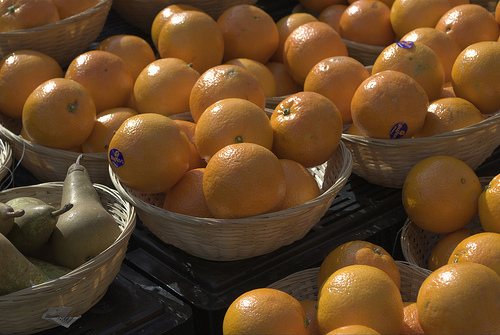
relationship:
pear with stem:
[46, 159, 128, 273] [73, 149, 89, 162]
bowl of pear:
[0, 177, 138, 333] [47, 149, 127, 268]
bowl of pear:
[0, 177, 138, 333] [0, 188, 74, 252]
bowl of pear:
[0, 177, 138, 333] [0, 224, 60, 295]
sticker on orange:
[382, 118, 410, 142] [347, 68, 430, 141]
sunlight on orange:
[144, 63, 165, 78] [128, 56, 206, 117]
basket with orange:
[103, 109, 360, 266] [196, 136, 287, 221]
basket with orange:
[103, 109, 360, 266] [108, 110, 195, 200]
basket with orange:
[103, 109, 360, 266] [268, 85, 347, 172]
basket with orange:
[103, 109, 360, 266] [187, 61, 271, 122]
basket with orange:
[103, 109, 360, 266] [188, 93, 280, 157]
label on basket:
[44, 306, 91, 333] [1, 178, 139, 333]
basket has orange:
[103, 109, 360, 266] [196, 141, 296, 221]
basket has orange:
[103, 109, 360, 266] [108, 110, 195, 200]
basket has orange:
[103, 109, 360, 266] [268, 85, 347, 172]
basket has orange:
[103, 109, 360, 266] [188, 93, 275, 167]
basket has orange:
[103, 109, 360, 266] [187, 61, 271, 122]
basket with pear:
[1, 178, 139, 333] [47, 149, 127, 268]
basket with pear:
[1, 178, 139, 333] [2, 192, 73, 255]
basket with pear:
[1, 178, 139, 333] [1, 229, 60, 299]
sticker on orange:
[105, 146, 130, 172] [108, 110, 195, 200]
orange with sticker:
[347, 68, 430, 141] [385, 120, 412, 140]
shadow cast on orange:
[315, 237, 362, 286] [220, 284, 313, 333]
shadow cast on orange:
[315, 237, 362, 286] [315, 261, 407, 332]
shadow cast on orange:
[315, 237, 362, 286] [312, 231, 410, 299]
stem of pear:
[50, 201, 72, 217] [2, 192, 73, 255]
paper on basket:
[37, 302, 84, 332] [1, 178, 139, 333]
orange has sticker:
[102, 109, 196, 196] [105, 146, 130, 172]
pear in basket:
[46, 153, 124, 272] [1, 178, 139, 333]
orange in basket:
[107, 112, 190, 195] [108, 157, 357, 260]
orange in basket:
[107, 112, 190, 195] [340, 119, 484, 203]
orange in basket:
[107, 112, 190, 195] [2, 122, 117, 188]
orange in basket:
[107, 112, 190, 195] [108, 133, 357, 263]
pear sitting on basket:
[46, 153, 124, 272] [103, 109, 360, 266]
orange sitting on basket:
[107, 112, 190, 195] [103, 109, 360, 266]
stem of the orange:
[66, 99, 78, 114] [23, 78, 94, 144]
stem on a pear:
[47, 200, 72, 224] [0, 191, 77, 257]